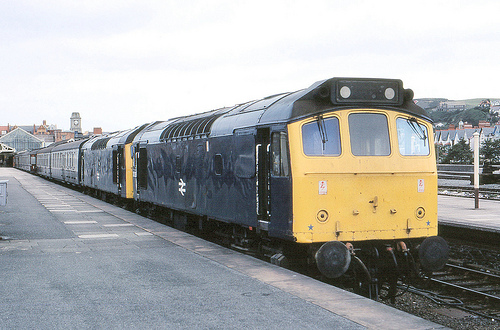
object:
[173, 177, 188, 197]
logo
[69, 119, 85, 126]
clock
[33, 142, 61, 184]
car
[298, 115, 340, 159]
windows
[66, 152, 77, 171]
windows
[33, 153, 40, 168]
windows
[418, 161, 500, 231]
ground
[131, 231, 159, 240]
rectangles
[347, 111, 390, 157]
windows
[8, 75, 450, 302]
train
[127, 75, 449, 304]
train car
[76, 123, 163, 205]
train car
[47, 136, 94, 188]
train car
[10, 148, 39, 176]
train car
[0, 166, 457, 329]
cement platform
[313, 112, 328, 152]
windshield wiper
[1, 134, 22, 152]
metal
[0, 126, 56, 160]
building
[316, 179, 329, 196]
stickers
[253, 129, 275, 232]
open door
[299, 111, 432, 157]
windshield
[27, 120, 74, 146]
building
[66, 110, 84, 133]
tower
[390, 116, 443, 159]
right windshield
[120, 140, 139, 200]
divider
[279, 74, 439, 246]
front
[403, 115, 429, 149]
windshield wiper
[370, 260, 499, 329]
train track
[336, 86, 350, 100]
headlight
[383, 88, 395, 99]
headlight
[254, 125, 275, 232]
area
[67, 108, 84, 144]
building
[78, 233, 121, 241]
rectangle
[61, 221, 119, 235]
rectangle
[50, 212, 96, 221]
rectangle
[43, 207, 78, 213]
rectangle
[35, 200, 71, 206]
rectangle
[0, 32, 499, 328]
train station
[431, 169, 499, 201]
train track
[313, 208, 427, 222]
indents